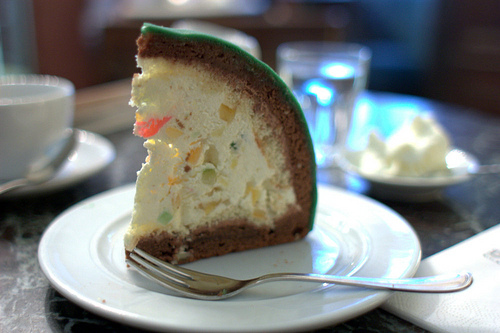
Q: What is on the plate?
A: Fork.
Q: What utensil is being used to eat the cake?
A: Fork.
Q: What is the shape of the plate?
A: Circle.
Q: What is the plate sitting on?
A: Table.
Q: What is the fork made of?
A: Metal.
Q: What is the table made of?
A: Granite.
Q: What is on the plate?
A: A piece of cake.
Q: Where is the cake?
A: On a white plate.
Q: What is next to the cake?
A: A fork.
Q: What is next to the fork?
A: A piece of cake.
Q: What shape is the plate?
A: Round.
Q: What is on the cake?
A: Frosting.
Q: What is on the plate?
A: A piece of cake and a fork.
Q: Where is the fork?
A: Next to the cake.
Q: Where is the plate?
A: On a table.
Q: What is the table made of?
A: Wood.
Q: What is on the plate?
A: Slice of cake.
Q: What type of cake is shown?
A: Easter cake.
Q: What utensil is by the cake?
A: A fork.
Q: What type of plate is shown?
A: White and round.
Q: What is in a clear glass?
A: Water.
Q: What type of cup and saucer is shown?
A: Coffee.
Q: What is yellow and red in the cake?
A: Fruit.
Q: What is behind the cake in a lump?
A: Butter.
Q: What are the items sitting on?
A: Black granite.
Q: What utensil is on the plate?
A: Fork.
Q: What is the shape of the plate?
A: Circle.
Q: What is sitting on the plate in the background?
A: A cup.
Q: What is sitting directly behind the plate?
A: A glass.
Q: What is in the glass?
A: Water/.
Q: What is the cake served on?
A: A plate.